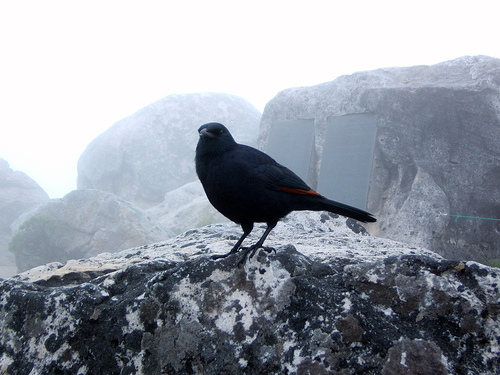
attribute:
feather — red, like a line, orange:
[275, 186, 322, 197]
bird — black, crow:
[194, 123, 378, 259]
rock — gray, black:
[2, 208, 498, 374]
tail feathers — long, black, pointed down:
[299, 195, 375, 227]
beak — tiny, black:
[197, 129, 209, 139]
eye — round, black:
[210, 127, 222, 136]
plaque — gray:
[264, 117, 318, 193]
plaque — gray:
[318, 114, 375, 212]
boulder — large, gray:
[8, 186, 172, 269]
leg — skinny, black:
[211, 221, 255, 259]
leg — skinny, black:
[237, 222, 278, 260]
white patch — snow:
[122, 304, 146, 333]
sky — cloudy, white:
[0, 1, 500, 202]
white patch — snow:
[245, 257, 290, 299]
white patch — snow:
[291, 346, 308, 366]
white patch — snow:
[422, 268, 438, 309]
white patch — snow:
[126, 349, 146, 374]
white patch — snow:
[102, 275, 116, 291]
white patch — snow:
[464, 259, 490, 270]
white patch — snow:
[213, 307, 239, 335]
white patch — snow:
[397, 352, 410, 369]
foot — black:
[240, 244, 266, 261]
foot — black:
[210, 253, 228, 262]